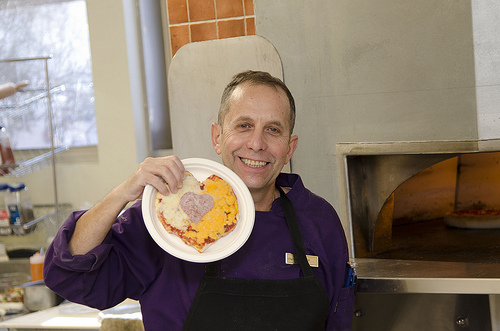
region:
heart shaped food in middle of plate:
[152, 165, 241, 260]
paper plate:
[135, 149, 256, 266]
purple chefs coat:
[40, 168, 360, 330]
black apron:
[175, 183, 325, 329]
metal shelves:
[2, 53, 72, 319]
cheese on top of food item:
[202, 179, 235, 199]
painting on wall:
[331, 130, 496, 288]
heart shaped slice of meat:
[176, 183, 219, 227]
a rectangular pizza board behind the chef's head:
[169, 36, 295, 171]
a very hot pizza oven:
[334, 137, 499, 295]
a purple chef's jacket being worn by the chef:
[43, 173, 355, 329]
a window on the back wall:
[1, 0, 95, 162]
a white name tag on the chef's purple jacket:
[284, 252, 323, 269]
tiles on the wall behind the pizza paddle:
[167, 1, 256, 58]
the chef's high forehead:
[227, 86, 292, 120]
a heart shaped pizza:
[152, 172, 237, 254]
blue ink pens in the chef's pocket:
[341, 263, 356, 290]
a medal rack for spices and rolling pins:
[1, 57, 71, 286]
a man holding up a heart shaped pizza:
[138, 81, 341, 330]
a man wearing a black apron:
[120, 66, 347, 328]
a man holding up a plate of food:
[117, 71, 361, 330]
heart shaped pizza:
[138, 156, 253, 260]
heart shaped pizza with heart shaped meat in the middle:
[140, 152, 251, 261]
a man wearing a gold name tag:
[83, 70, 361, 330]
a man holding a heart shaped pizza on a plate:
[82, 81, 368, 322]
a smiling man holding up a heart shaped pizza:
[79, 73, 348, 323]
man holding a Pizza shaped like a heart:
[126, 145, 258, 262]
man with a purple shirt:
[243, 177, 353, 294]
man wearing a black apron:
[184, 265, 332, 328]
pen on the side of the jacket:
[333, 252, 365, 292]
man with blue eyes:
[226, 114, 278, 141]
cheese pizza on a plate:
[158, 160, 240, 249]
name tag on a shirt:
[282, 244, 326, 270]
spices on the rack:
[1, 128, 35, 241]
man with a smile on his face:
[231, 144, 283, 181]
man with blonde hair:
[203, 63, 298, 139]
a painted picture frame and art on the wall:
[333, 137, 499, 300]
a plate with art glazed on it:
[141, 157, 254, 262]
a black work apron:
[177, 262, 337, 329]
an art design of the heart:
[158, 169, 237, 255]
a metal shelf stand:
[1, 55, 74, 235]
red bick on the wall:
[166, 0, 257, 40]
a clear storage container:
[4, 180, 35, 235]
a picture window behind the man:
[28, 2, 100, 149]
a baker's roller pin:
[1, 79, 31, 99]